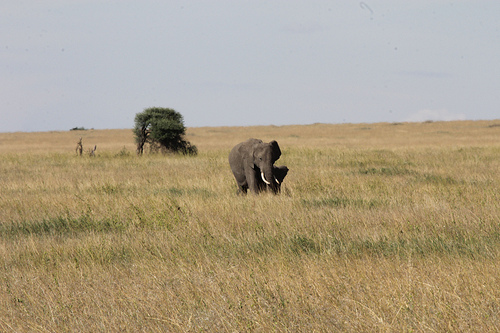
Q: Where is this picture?
A: Africa.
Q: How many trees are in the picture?
A: One.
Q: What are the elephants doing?
A: Walking.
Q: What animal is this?
A: Elephant.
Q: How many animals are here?
A: Two.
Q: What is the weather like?
A: Sunny.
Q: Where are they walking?
A: Grass.